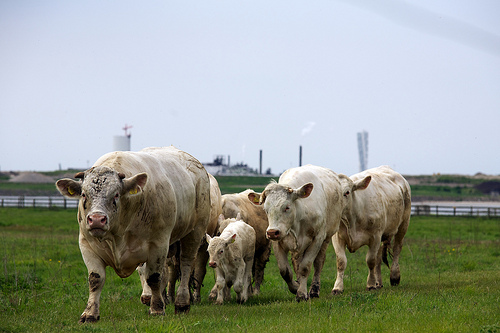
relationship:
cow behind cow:
[204, 219, 256, 303] [249, 163, 344, 303]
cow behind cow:
[134, 171, 223, 308] [54, 144, 213, 325]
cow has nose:
[54, 144, 213, 325] [86, 213, 109, 230]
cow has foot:
[204, 219, 256, 303] [214, 298, 225, 305]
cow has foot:
[204, 219, 256, 303] [235, 295, 246, 305]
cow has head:
[54, 144, 213, 325] [55, 165, 149, 238]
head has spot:
[55, 165, 149, 238] [82, 197, 89, 210]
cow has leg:
[54, 144, 213, 325] [78, 244, 106, 323]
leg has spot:
[78, 244, 106, 323] [88, 271, 102, 280]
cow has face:
[204, 219, 256, 303] [206, 245, 226, 269]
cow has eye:
[54, 144, 213, 325] [80, 191, 88, 198]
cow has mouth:
[54, 144, 213, 325] [85, 226, 110, 234]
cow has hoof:
[54, 144, 213, 325] [79, 313, 101, 324]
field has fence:
[1, 206, 499, 331] [0, 195, 499, 219]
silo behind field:
[112, 123, 134, 152] [1, 206, 499, 331]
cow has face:
[54, 144, 213, 325] [79, 188, 123, 237]